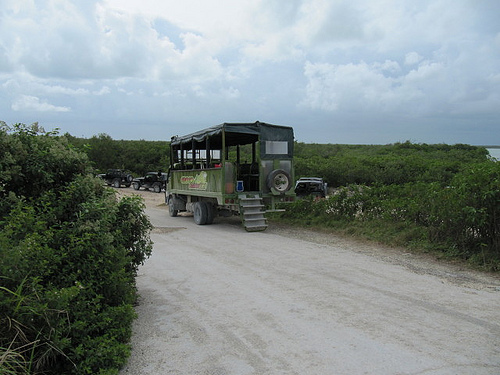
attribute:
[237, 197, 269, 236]
steps — small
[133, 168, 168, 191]
vehicle — black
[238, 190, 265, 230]
steps — grey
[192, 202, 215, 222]
tire — black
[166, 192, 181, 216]
tire — black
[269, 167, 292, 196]
tire — black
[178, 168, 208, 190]
logo — green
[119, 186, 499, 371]
road — dirt, narrow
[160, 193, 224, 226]
wheels — these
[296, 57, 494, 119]
clouds — puffy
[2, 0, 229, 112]
clouds — puffy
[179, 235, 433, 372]
road — light brown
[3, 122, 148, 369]
bushes — green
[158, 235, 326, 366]
road — dusty, dry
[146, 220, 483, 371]
road — narrow, dirt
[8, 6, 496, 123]
sky — cloudy